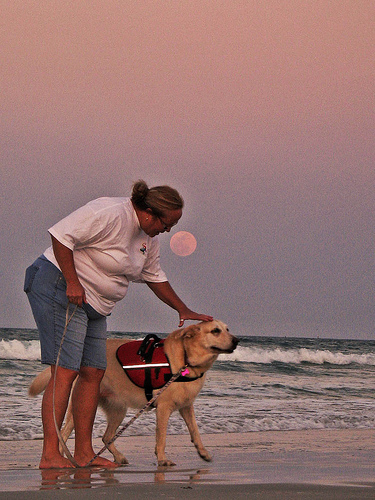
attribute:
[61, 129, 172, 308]
woman — big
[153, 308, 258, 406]
dog — brown, black, close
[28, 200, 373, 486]
beach — brown, wet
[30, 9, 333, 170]
sky — light, purple, blue, dark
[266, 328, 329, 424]
water — blue, close, white, rapid, crashing, splashing